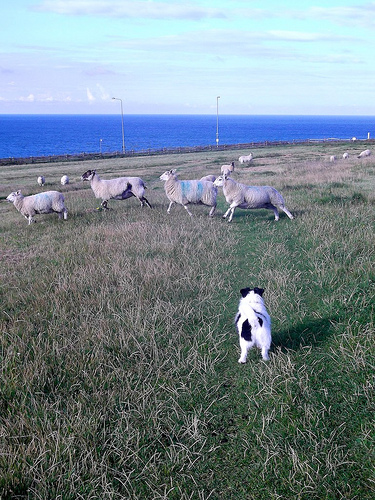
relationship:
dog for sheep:
[238, 283, 283, 375] [14, 166, 284, 230]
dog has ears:
[238, 283, 283, 375] [240, 283, 274, 303]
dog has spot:
[238, 283, 283, 375] [237, 318, 262, 343]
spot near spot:
[237, 318, 262, 343] [237, 318, 262, 343]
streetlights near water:
[103, 87, 226, 157] [2, 107, 88, 159]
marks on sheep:
[174, 179, 210, 203] [14, 166, 284, 230]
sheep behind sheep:
[217, 130, 374, 175] [14, 166, 284, 230]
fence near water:
[10, 148, 155, 166] [2, 107, 88, 159]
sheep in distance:
[217, 130, 374, 175] [103, 138, 372, 173]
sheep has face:
[77, 161, 158, 212] [76, 166, 106, 191]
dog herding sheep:
[238, 283, 283, 375] [14, 166, 284, 230]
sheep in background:
[217, 130, 374, 175] [54, 124, 367, 177]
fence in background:
[10, 148, 155, 166] [54, 124, 367, 177]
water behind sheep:
[2, 107, 88, 159] [14, 166, 284, 230]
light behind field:
[108, 84, 139, 160] [73, 157, 252, 173]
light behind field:
[205, 88, 230, 145] [73, 157, 252, 173]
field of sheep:
[73, 157, 252, 173] [14, 166, 284, 230]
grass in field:
[31, 235, 213, 418] [73, 157, 252, 173]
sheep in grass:
[14, 166, 284, 230] [31, 235, 213, 418]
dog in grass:
[238, 283, 283, 375] [31, 235, 213, 418]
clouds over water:
[64, 10, 194, 85] [2, 107, 88, 159]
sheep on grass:
[14, 166, 284, 230] [31, 235, 213, 418]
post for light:
[116, 96, 134, 151] [108, 84, 139, 160]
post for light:
[214, 102, 230, 146] [205, 88, 230, 145]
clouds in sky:
[155, 17, 277, 64] [64, 10, 194, 85]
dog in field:
[238, 283, 283, 375] [73, 157, 252, 173]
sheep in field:
[14, 166, 284, 230] [73, 157, 252, 173]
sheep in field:
[217, 130, 374, 175] [73, 157, 252, 173]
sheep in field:
[160, 157, 226, 220] [73, 157, 252, 173]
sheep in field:
[10, 185, 75, 231] [73, 157, 252, 173]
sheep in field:
[320, 140, 373, 178] [73, 157, 252, 173]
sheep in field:
[230, 146, 259, 171] [73, 157, 252, 173]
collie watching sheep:
[238, 283, 283, 375] [14, 166, 284, 230]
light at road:
[108, 84, 139, 160] [65, 147, 265, 162]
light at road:
[205, 88, 230, 145] [65, 147, 265, 162]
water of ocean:
[2, 107, 88, 159] [37, 98, 285, 155]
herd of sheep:
[35, 114, 285, 236] [14, 166, 284, 230]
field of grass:
[73, 157, 252, 173] [31, 235, 213, 418]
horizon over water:
[15, 101, 326, 130] [2, 107, 88, 159]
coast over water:
[32, 144, 335, 167] [2, 107, 88, 159]